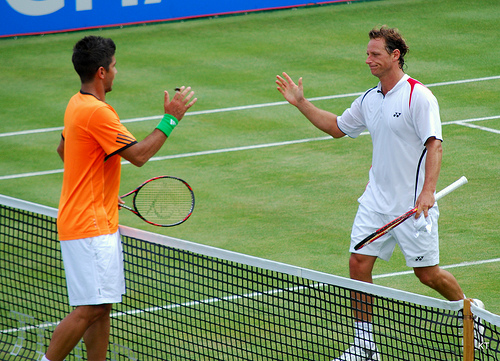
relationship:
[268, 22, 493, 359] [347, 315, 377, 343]
man wearing sock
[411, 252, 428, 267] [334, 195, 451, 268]
logo on shorts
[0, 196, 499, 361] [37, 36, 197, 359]
net between player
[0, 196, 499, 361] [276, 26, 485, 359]
net between player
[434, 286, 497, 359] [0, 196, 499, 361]
pole holding net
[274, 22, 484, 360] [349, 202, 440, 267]
man wearing shorts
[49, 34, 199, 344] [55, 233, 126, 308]
man wearing white shorts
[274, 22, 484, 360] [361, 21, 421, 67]
man has blonde hair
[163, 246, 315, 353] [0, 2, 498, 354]
net on court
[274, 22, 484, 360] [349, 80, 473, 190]
man wearing a shirt